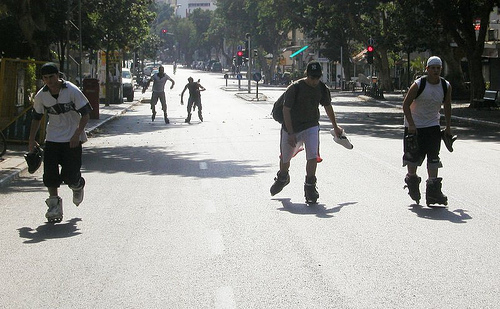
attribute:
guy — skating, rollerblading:
[269, 61, 354, 210]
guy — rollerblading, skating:
[402, 53, 457, 209]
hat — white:
[423, 52, 447, 72]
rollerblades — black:
[267, 171, 322, 208]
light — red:
[235, 49, 246, 67]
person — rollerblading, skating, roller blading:
[179, 76, 205, 122]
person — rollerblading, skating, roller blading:
[142, 66, 176, 125]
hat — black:
[306, 58, 322, 78]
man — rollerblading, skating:
[24, 60, 92, 224]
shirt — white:
[31, 84, 89, 143]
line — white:
[193, 155, 242, 306]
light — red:
[362, 46, 376, 65]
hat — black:
[38, 63, 58, 77]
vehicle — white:
[117, 64, 133, 98]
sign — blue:
[252, 72, 263, 96]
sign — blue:
[235, 72, 245, 92]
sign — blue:
[224, 72, 230, 86]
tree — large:
[389, 0, 498, 106]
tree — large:
[291, 1, 368, 94]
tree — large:
[251, 4, 304, 88]